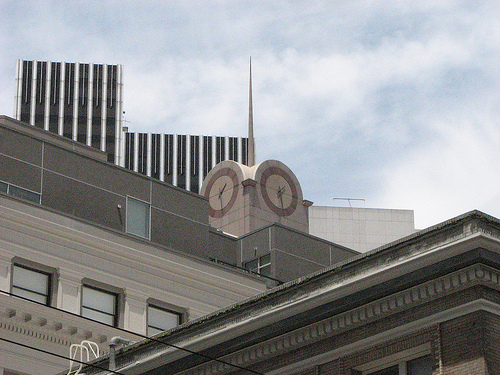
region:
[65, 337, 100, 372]
The white ladder on the near building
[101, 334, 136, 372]
The silver pipe on the near building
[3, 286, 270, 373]
The wires in front of the buildings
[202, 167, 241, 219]
The clock on the left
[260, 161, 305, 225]
The clock on the right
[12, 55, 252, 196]
The tall black and white building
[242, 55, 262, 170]
The spire on top of the clock tower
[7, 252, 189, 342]
The line of three windows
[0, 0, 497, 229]
The cloud filled sky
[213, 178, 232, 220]
The hands on the clock to the left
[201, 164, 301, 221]
Two clocks side by side.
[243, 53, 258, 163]
A tall skinny point on atop a building.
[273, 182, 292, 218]
Black metal clock hands.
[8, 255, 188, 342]
Three windows in a row.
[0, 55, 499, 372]
The top view of several buildings.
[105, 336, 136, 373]
A pipe on the roof of a building.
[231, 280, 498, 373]
Brick on a building.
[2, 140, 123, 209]
White paint lines on a building.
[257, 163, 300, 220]
A circle made of bricks.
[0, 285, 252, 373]
Wires attached to the side of a building.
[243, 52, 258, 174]
The needle on top of the clock tower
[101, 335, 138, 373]
The grey pipe on the nearest building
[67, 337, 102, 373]
The white ladder on the nearest building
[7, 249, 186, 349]
The row of three windows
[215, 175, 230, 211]
The hands on the left clock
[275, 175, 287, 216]
The hands on the right clock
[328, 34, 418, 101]
white cloud in the sky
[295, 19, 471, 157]
many clouds in the sky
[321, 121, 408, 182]
blue sky behind clouds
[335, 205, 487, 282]
edge of a building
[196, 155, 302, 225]
two clocks on a building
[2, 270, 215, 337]
three windows on a building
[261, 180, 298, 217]
hand of the clock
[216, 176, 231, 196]
little hand of clock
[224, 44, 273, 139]
tip of the building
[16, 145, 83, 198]
lines on the building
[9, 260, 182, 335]
Windows on the building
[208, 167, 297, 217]
A clock above the building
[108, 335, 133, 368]
A pipe on top of the building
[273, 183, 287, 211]
The hands of the clock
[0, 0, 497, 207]
The sky above the buildings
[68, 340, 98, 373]
A ladder leading to the roof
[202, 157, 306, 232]
The clocktower is made of stone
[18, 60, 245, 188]
Buildings towering above the clocktower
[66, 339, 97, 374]
The ladder is white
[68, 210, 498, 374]
The edge of the rooftop